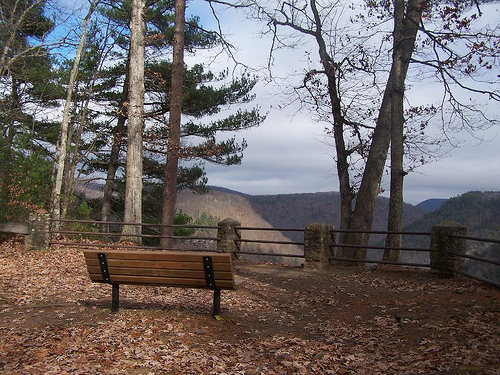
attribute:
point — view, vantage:
[86, 222, 326, 311]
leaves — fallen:
[115, 313, 315, 370]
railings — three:
[242, 222, 304, 234]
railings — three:
[249, 236, 301, 248]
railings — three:
[240, 248, 302, 262]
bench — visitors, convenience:
[82, 232, 256, 324]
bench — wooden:
[77, 247, 253, 301]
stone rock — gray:
[427, 216, 472, 276]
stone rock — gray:
[299, 220, 344, 272]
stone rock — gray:
[212, 214, 244, 265]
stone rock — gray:
[23, 206, 60, 253]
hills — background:
[124, 184, 498, 262]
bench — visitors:
[67, 232, 270, 329]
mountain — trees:
[68, 170, 498, 283]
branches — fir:
[169, 61, 268, 199]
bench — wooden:
[80, 251, 236, 322]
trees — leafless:
[328, 0, 489, 268]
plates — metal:
[96, 248, 223, 285]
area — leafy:
[25, 248, 415, 362]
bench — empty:
[77, 243, 239, 319]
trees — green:
[67, 11, 188, 216]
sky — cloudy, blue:
[275, 121, 311, 183]